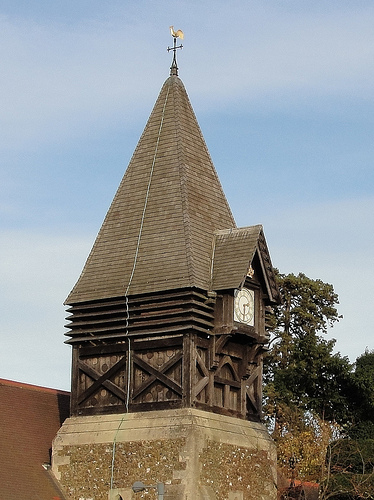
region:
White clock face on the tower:
[231, 287, 253, 324]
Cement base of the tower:
[51, 408, 275, 497]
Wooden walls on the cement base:
[69, 335, 264, 422]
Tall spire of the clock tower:
[63, 76, 278, 304]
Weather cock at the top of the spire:
[166, 24, 184, 52]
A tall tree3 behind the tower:
[261, 268, 349, 435]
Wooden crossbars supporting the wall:
[132, 346, 182, 399]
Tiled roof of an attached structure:
[0, 377, 70, 498]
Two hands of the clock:
[243, 302, 249, 315]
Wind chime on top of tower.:
[160, 24, 188, 69]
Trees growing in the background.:
[282, 311, 369, 498]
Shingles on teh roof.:
[2, 386, 54, 443]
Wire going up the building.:
[120, 291, 138, 421]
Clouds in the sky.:
[242, 32, 344, 135]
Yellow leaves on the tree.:
[283, 426, 326, 481]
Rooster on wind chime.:
[170, 23, 188, 44]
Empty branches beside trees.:
[330, 443, 372, 498]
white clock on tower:
[237, 286, 254, 325]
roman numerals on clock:
[228, 281, 254, 316]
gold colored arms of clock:
[239, 301, 252, 322]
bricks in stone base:
[174, 416, 253, 440]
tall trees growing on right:
[279, 268, 373, 473]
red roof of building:
[1, 379, 66, 490]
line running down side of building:
[99, 422, 138, 498]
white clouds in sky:
[20, 225, 81, 335]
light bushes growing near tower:
[266, 416, 327, 493]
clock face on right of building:
[234, 290, 254, 321]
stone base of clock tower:
[63, 414, 220, 497]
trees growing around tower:
[276, 268, 351, 414]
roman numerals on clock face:
[237, 294, 253, 318]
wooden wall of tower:
[84, 348, 192, 405]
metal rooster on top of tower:
[159, 14, 197, 55]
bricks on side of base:
[205, 413, 271, 442]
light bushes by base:
[286, 431, 330, 487]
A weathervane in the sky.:
[161, 20, 185, 75]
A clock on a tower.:
[63, 77, 279, 415]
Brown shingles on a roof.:
[1, 377, 88, 497]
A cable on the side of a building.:
[63, 76, 278, 498]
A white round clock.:
[230, 285, 256, 328]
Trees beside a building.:
[63, 22, 372, 493]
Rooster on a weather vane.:
[165, 23, 184, 74]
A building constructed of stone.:
[51, 408, 275, 498]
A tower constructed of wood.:
[64, 72, 267, 420]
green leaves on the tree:
[357, 367, 373, 405]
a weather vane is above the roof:
[164, 28, 184, 64]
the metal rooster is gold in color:
[168, 25, 183, 39]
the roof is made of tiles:
[63, 76, 269, 292]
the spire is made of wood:
[57, 286, 270, 420]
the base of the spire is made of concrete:
[49, 407, 280, 496]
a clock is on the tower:
[229, 282, 262, 332]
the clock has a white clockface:
[232, 284, 256, 325]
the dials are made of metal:
[238, 300, 254, 322]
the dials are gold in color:
[241, 299, 247, 317]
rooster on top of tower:
[164, 23, 187, 43]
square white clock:
[232, 287, 256, 328]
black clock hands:
[239, 302, 253, 321]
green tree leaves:
[265, 266, 371, 496]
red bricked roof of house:
[0, 375, 72, 497]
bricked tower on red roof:
[51, 71, 281, 497]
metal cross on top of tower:
[166, 34, 184, 64]